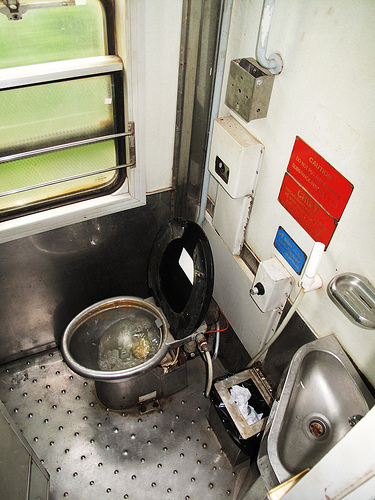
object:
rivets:
[33, 398, 184, 473]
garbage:
[228, 385, 264, 424]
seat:
[144, 215, 215, 339]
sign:
[271, 226, 307, 276]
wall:
[193, 0, 375, 367]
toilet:
[0, 0, 374, 500]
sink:
[264, 329, 375, 485]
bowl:
[59, 293, 169, 379]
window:
[0, 0, 134, 217]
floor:
[0, 344, 248, 500]